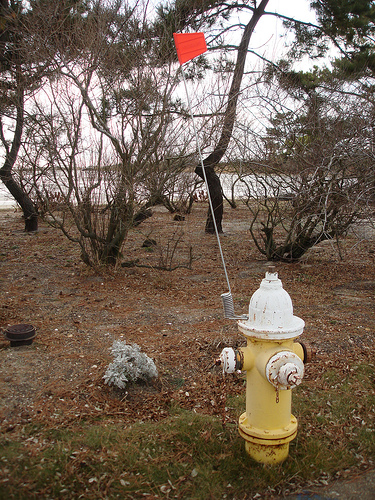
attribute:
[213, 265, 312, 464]
hydrant — yellow, white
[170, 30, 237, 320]
flag — red, plastic, orange, small, flying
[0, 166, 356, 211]
lake — clear, gray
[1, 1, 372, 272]
trees — bare, brown, wooden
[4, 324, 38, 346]
pipe — brown, metal, dark brown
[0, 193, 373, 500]
ground — dirty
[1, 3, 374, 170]
sky — clear, bright, white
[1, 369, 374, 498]
grass — green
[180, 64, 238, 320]
pole — silver, metal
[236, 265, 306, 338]
top — white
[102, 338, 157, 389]
bush — white, foliage, small, plant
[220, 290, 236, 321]
coil — metal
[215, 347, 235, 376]
cap — white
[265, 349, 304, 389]
cap — white